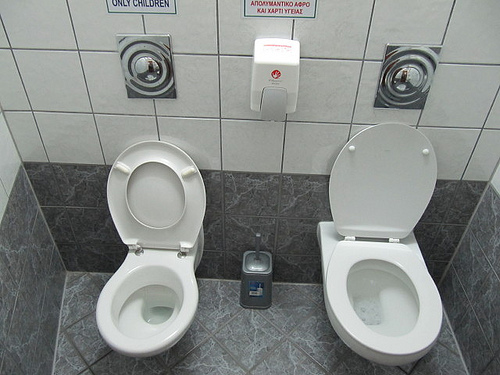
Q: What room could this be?
A: It is a bathroom.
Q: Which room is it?
A: It is a bathroom.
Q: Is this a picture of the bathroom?
A: Yes, it is showing the bathroom.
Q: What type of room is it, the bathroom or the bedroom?
A: It is the bathroom.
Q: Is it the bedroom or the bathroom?
A: It is the bathroom.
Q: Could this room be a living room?
A: No, it is a bathroom.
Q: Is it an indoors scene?
A: Yes, it is indoors.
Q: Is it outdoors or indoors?
A: It is indoors.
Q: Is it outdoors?
A: No, it is indoors.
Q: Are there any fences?
A: No, there are no fences.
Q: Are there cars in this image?
A: No, there are no cars.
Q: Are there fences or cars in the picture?
A: No, there are no cars or fences.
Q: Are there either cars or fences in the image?
A: No, there are no cars or fences.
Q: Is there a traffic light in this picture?
A: No, there are no traffic lights.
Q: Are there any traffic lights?
A: No, there are no traffic lights.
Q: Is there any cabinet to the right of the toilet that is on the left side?
A: No, there is a toilet brush to the right of the toilet.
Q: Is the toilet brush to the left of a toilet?
A: No, the toilet brush is to the right of a toilet.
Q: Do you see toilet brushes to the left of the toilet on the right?
A: Yes, there is a toilet brush to the left of the toilet.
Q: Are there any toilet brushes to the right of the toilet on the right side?
A: No, the toilet brush is to the left of the toilet.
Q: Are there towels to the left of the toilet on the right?
A: No, there is a toilet brush to the left of the toilet.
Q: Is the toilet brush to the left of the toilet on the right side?
A: Yes, the toilet brush is to the left of the toilet.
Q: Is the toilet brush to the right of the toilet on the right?
A: No, the toilet brush is to the left of the toilet.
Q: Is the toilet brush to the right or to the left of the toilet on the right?
A: The toilet brush is to the left of the toilet.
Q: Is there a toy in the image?
A: No, there are no toys.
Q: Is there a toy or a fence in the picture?
A: No, there are no toys or fences.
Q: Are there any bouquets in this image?
A: No, there are no bouquets.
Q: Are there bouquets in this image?
A: No, there are no bouquets.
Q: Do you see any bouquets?
A: No, there are no bouquets.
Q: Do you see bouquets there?
A: No, there are no bouquets.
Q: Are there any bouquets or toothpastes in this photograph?
A: No, there are no bouquets or toothpastes.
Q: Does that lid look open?
A: Yes, the lid is open.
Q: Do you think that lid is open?
A: Yes, the lid is open.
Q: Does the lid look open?
A: Yes, the lid is open.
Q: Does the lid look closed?
A: No, the lid is open.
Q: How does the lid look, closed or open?
A: The lid is open.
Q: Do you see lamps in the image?
A: No, there are no lamps.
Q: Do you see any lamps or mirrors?
A: No, there are no lamps or mirrors.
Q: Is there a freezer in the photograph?
A: No, there are no refrigerators.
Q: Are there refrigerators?
A: No, there are no refrigerators.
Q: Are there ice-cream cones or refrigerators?
A: No, there are no refrigerators or ice-cream cones.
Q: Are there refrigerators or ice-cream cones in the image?
A: No, there are no refrigerators or ice-cream cones.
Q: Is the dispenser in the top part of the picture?
A: Yes, the dispenser is in the top of the image.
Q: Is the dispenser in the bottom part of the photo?
A: No, the dispenser is in the top of the image.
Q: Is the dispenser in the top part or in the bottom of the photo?
A: The dispenser is in the top of the image.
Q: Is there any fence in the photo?
A: No, there are no fences.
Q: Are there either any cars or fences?
A: No, there are no fences or cars.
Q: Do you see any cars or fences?
A: No, there are no fences or cars.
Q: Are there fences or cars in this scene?
A: No, there are no fences or cars.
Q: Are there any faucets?
A: No, there are no faucets.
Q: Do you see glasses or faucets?
A: No, there are no faucets or glasses.